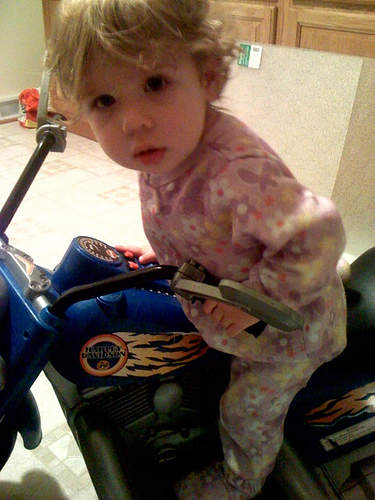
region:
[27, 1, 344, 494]
a biker-in-training on a kid version of a hog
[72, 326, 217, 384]
the little kid bike has the Harley Davidson logo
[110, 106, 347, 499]
the little girl is in her jammies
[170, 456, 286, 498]
the little girl's jammies have feet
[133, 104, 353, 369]
the little girl's jammies have a flower print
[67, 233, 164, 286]
the kid-Harley has a little pretend speedometer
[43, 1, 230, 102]
the little girl has blond hair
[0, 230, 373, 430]
the little kid Harley is blue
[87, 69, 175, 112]
the little girl has big dark Bambi eyes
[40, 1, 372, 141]
wooden cabinet behind the little girl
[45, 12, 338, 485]
Baby on a motorcycle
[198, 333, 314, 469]
baby wearing pink pants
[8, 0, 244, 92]
baby with blonde hair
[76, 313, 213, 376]
flame on a bike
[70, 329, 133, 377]
Harley Davidson sign on a bike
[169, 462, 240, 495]
Baby wear pink foot socks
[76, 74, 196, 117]
baby with brown eyes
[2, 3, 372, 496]
A toddler on a toy motorbike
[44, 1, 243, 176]
Blonde hair on toddler's head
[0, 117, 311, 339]
Handlebars of a toy motorbike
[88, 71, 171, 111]
A pair of brown eyes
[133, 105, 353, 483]
A pink outfit with flower designs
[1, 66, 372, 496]
The toy motorbike is blue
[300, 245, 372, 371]
The seat is leather and black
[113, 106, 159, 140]
Nose on the toddler's face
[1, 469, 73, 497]
A shadow on the floor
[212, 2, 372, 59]
A brown and wooden cabinet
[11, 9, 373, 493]
TODDLER RIDING A TOY BIKE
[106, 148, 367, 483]
girl is wearing pajamas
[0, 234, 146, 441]
the bike is blue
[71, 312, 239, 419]
bike has flames on it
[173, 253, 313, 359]
bike handles are gray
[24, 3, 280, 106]
girl has light brown hair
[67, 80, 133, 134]
girl has brown eyes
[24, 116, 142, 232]
the floor is tile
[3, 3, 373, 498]
a baby sit on a toy motorcycle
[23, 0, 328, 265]
toddler is blonde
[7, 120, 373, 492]
toy motorcycle is color blue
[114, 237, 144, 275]
red buttons on toy motorcycle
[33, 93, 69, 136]
left handle of toy motorcycle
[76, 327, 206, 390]
toy motorcycle has a design on side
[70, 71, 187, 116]
eyes are brown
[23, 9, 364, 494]
toddler wears purple clothes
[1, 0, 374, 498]
baby riding toy motorcycle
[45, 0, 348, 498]
baby wearing pink floral pajamas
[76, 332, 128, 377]
circular orange harley davidson logo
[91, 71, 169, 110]
two brown baby eyes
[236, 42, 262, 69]
green and white tag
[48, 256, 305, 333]
black handlebar with silver side mirror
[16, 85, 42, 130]
red bag on top of floor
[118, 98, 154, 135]
Nose on a little girl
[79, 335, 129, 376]
Circle that says HARLEY DAVIDSON inside it.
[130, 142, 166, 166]
Pink lips of a child.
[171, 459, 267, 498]
A child's left foot slipper.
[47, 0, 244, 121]
Blonde hair of a child.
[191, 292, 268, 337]
Black handlebar with fingers on it.